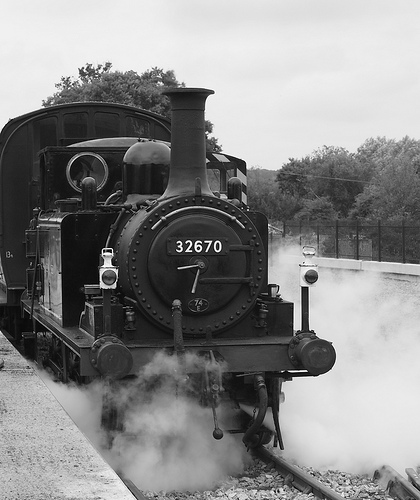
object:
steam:
[27, 346, 247, 492]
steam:
[262, 235, 419, 472]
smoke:
[30, 245, 419, 496]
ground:
[0, 267, 420, 500]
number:
[176, 240, 222, 253]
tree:
[42, 62, 222, 151]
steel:
[272, 456, 294, 483]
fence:
[271, 219, 420, 264]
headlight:
[305, 269, 318, 283]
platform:
[0, 332, 137, 500]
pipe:
[242, 379, 268, 444]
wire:
[275, 171, 380, 186]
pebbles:
[138, 446, 384, 500]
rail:
[115, 444, 344, 500]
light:
[99, 248, 119, 289]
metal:
[26, 185, 248, 362]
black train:
[0, 87, 336, 451]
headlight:
[102, 269, 116, 285]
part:
[260, 395, 267, 409]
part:
[142, 243, 177, 291]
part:
[138, 405, 200, 462]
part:
[274, 455, 299, 489]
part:
[229, 471, 258, 489]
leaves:
[40, 61, 220, 153]